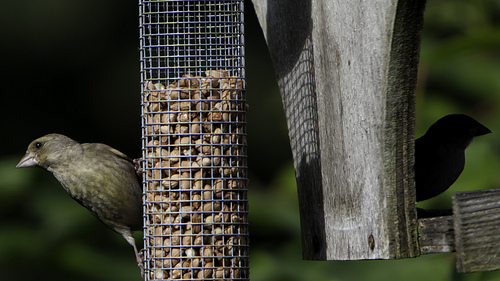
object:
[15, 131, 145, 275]
bird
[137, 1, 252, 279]
wire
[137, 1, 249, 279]
bird feeder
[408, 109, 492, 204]
shadow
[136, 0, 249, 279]
wire box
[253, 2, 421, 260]
gray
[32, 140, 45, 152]
eye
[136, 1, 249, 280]
tube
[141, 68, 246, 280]
beans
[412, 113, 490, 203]
bird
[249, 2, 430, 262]
plank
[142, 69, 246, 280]
feed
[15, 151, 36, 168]
beak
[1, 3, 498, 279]
foilage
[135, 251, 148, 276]
talon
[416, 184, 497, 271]
bracket feeder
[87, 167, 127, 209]
belly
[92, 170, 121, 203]
feathers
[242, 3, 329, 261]
reflection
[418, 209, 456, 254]
holder